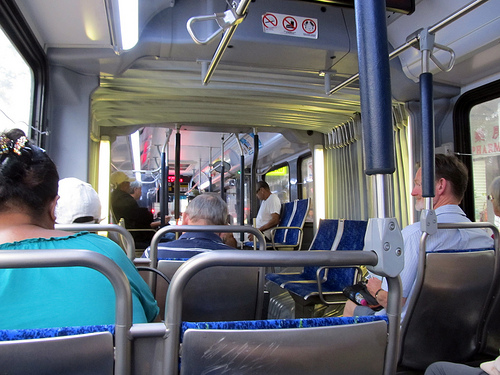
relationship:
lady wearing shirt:
[0, 124, 160, 333] [0, 234, 162, 345]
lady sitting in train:
[0, 124, 160, 333] [0, 0, 490, 366]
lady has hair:
[0, 124, 160, 333] [0, 124, 68, 230]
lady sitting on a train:
[0, 124, 160, 333] [0, 0, 490, 366]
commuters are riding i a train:
[0, 132, 468, 334] [0, 0, 490, 366]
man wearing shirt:
[243, 178, 284, 244] [257, 186, 289, 250]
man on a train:
[243, 178, 284, 244] [0, 0, 490, 366]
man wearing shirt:
[141, 191, 242, 261] [152, 228, 246, 254]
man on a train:
[141, 191, 242, 261] [0, 0, 490, 366]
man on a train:
[343, 148, 494, 317] [0, 0, 490, 366]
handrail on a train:
[185, 8, 248, 54] [0, 0, 490, 366]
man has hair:
[147, 188, 257, 260] [180, 188, 238, 222]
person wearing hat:
[45, 178, 159, 318] [56, 174, 104, 228]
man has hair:
[343, 148, 494, 317] [424, 148, 468, 203]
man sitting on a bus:
[243, 178, 284, 244] [260, 199, 316, 251]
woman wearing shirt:
[5, 121, 155, 337] [0, 234, 162, 345]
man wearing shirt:
[141, 191, 242, 261] [158, 223, 246, 263]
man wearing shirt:
[343, 148, 494, 317] [371, 200, 483, 293]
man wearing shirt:
[225, 178, 292, 255] [254, 189, 296, 237]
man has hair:
[343, 148, 494, 317] [427, 150, 465, 213]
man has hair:
[141, 191, 242, 261] [188, 190, 231, 229]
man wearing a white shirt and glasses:
[243, 178, 284, 244] [248, 185, 259, 207]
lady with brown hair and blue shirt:
[5, 124, 154, 375] [2, 266, 108, 347]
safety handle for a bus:
[176, 50, 200, 52] [5, 142, 447, 375]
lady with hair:
[0, 124, 160, 333] [0, 125, 37, 165]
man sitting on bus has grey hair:
[141, 191, 242, 261] [192, 195, 221, 215]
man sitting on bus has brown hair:
[404, 148, 494, 280] [441, 152, 474, 193]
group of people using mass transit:
[2, 137, 478, 329] [129, 107, 274, 147]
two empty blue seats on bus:
[159, 168, 379, 352] [72, 102, 398, 375]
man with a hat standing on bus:
[243, 178, 284, 244] [249, 163, 270, 203]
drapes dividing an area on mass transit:
[245, 50, 427, 183] [27, 124, 352, 354]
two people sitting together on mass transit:
[115, 174, 163, 235] [50, 175, 466, 375]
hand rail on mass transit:
[404, 50, 469, 149] [86, 105, 354, 264]